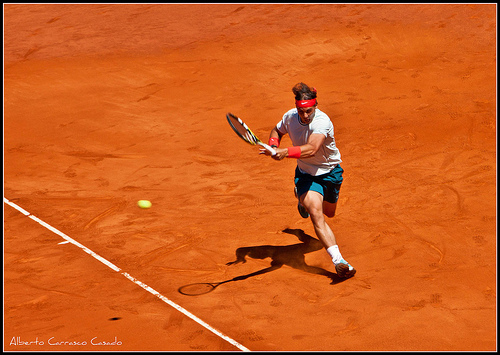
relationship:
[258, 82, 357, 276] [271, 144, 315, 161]
player has hand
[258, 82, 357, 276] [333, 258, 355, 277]
player has foot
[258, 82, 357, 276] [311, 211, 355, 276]
player has leg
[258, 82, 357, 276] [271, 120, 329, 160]
player has arm